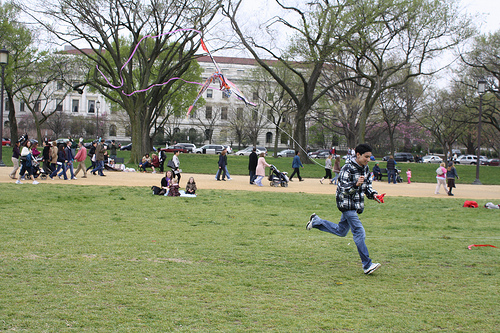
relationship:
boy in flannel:
[305, 136, 422, 295] [343, 162, 391, 212]